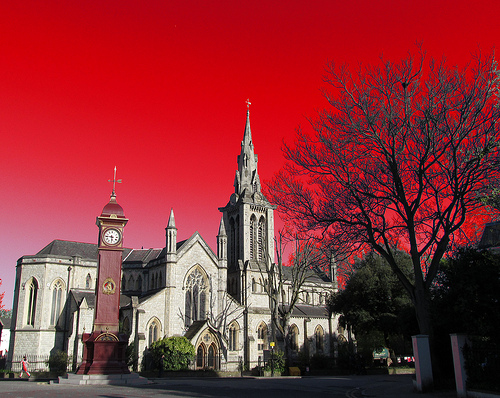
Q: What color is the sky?
A: Red.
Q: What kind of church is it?
A: A basilica.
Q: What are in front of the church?
A: Bushes.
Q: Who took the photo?
A: A professional photographer.